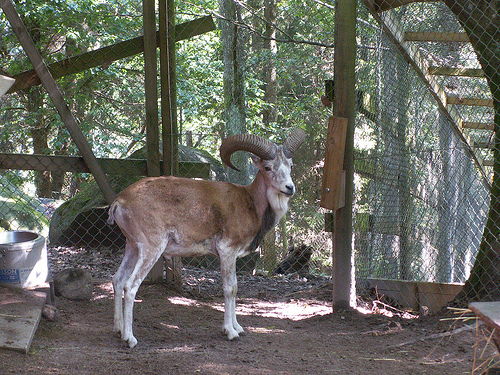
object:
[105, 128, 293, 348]
goat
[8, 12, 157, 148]
fence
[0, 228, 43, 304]
bucket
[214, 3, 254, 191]
tree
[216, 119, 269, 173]
horns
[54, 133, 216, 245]
rock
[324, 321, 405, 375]
dirt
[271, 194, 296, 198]
chin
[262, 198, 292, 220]
hair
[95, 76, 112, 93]
leaves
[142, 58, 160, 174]
wood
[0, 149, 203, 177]
boards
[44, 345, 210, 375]
ground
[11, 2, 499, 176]
background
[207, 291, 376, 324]
reflection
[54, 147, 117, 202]
mold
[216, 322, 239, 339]
feet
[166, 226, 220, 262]
stomach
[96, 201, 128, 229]
tail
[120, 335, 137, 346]
hoof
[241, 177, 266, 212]
neck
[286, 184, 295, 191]
nose